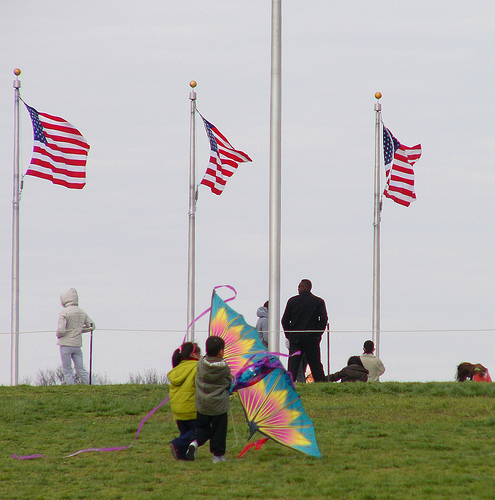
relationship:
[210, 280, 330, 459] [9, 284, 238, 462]
kite with tail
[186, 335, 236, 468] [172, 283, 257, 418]
boy in jacket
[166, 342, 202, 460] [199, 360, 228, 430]
child in jacket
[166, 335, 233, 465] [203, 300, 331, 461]
children holding kites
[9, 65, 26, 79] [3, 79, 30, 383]
ball on pole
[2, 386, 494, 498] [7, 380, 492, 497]
grass on hill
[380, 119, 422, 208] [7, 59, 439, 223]
flag in wind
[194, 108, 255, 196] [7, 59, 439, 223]
flag in wind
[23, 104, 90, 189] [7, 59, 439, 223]
flag in wind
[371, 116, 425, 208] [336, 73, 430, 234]
flag in wind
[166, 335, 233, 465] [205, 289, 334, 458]
children carry kite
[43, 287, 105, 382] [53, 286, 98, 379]
person wears outfit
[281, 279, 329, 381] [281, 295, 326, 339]
person wears jacket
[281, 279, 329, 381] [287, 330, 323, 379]
person wears pants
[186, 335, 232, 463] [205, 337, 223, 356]
boy has hair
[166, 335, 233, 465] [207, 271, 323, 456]
children carry kite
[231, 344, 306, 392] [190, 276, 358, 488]
ribbons on kite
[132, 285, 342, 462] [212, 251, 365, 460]
children holds kites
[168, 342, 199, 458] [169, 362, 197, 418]
child wearing jacket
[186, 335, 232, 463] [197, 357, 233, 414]
boy wearing jacket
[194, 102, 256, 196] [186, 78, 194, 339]
flag on pole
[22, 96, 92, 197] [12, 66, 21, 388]
flag on pole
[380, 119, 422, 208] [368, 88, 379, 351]
flag on pole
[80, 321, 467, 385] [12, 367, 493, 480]
fence on top of hill